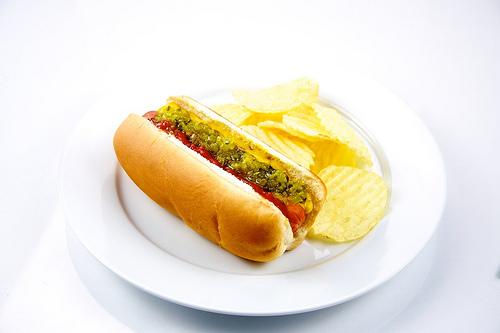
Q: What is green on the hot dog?
A: Relish.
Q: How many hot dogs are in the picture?
A: One.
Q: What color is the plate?
A: White.